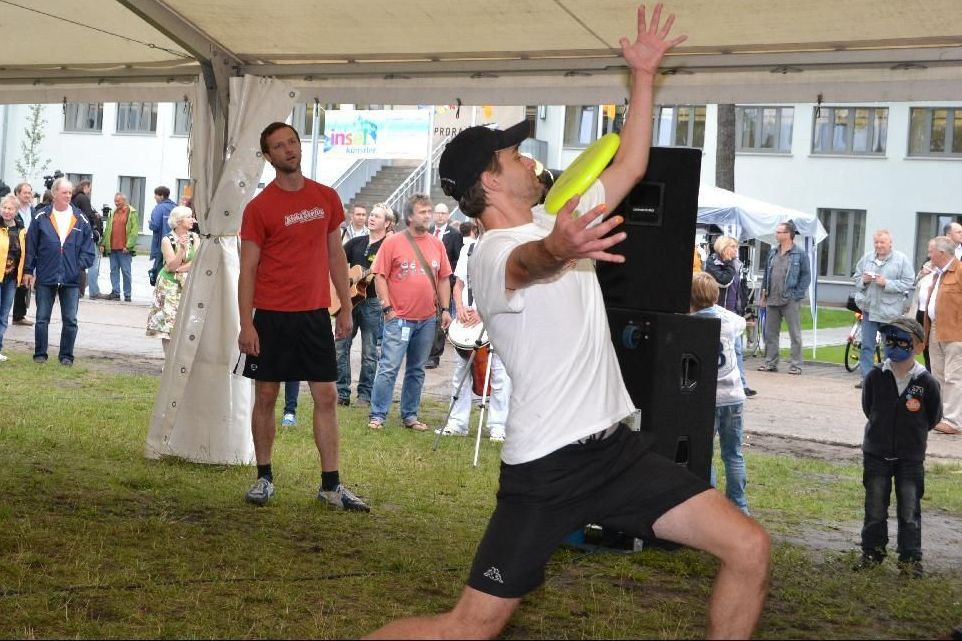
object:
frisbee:
[540, 133, 620, 216]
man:
[232, 122, 376, 513]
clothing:
[232, 176, 339, 383]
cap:
[432, 114, 537, 195]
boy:
[861, 317, 941, 576]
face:
[881, 326, 918, 362]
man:
[367, 197, 454, 432]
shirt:
[370, 231, 454, 321]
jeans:
[371, 316, 438, 419]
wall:
[0, 105, 188, 304]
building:
[0, 103, 962, 325]